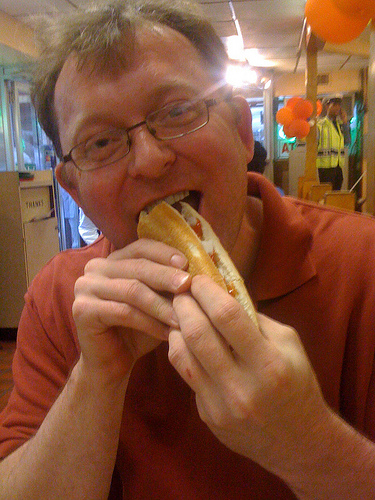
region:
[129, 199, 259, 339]
Hot dog in a bun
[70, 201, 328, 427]
hands holding hot dog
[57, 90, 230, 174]
Man with glasses on face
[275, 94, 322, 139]
Orange balloons on display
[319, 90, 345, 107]
White uniform cap on man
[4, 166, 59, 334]
Restaurant waste can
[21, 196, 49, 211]
Thanks written on restaurant waste can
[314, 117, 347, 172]
Reflective safety vest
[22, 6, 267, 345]
Man eating hot dog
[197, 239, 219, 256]
Onion topping on hot dog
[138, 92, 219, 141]
the eye of a man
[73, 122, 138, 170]
the eye of a man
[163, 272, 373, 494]
the hand of a man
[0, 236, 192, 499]
the hand of a man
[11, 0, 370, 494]
the man is eating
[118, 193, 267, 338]
this is a hot dog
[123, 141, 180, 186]
the nose of a man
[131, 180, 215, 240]
the mouth of a man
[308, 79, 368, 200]
this is a man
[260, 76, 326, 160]
these are orange baloons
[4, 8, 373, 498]
man eating a hot dog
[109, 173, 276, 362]
hot dog in a mouth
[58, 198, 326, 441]
hands holding a hot dog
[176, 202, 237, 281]
diced onions on hot dog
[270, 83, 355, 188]
orange balloons near a man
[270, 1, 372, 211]
two balloons hung from ceiling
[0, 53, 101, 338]
a trash can inside a restaurant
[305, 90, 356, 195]
man wearing a green vest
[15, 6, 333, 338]
man wears glasses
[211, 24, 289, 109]
light in the floor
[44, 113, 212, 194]
a man wearing glasses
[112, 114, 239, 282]
a man eating a hot dog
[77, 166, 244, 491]
a man holding a hot dog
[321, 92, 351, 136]
a man using a cell phone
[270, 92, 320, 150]
a bunch of orange balloons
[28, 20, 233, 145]
a man with short hair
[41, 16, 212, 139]
a man with brown hair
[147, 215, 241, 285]
a hot dog bun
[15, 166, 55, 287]
a trash containger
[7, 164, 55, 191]
plastic food trays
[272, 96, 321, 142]
cluster of orange balloons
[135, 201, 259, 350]
hot dog with ketchup and onions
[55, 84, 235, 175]
eyeglasses on man's face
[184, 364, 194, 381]
cut on man's finger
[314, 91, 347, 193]
man in yellow safety vest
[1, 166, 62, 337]
tall beige trash receptacle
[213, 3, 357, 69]
tiles in drop ceiling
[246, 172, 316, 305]
collar on brown shirt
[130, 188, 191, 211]
teeth in an open mouth